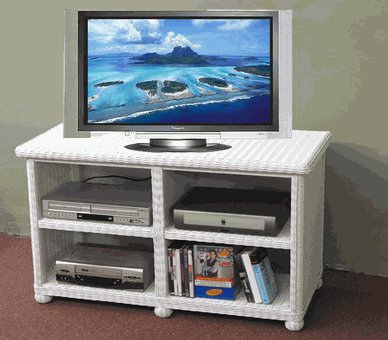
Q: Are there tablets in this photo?
A: No, there are no tablets.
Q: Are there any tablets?
A: No, there are no tablets.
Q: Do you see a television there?
A: Yes, there is a television.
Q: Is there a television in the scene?
A: Yes, there is a television.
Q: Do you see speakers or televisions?
A: Yes, there is a television.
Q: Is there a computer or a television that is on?
A: Yes, the television is on.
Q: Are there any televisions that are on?
A: Yes, there is a television that is on.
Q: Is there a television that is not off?
A: Yes, there is a television that is on.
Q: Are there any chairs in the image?
A: No, there are no chairs.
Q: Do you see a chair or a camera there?
A: No, there are no chairs or cameras.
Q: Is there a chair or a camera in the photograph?
A: No, there are no chairs or cameras.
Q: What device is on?
A: The device is a television.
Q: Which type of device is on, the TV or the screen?
A: The TV is on.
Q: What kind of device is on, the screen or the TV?
A: The TV is on.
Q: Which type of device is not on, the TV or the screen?
A: The screen is not on.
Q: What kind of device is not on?
A: The device is a screen.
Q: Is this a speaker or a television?
A: This is a television.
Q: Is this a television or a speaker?
A: This is a television.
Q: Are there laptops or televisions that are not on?
A: No, there is a television but it is on.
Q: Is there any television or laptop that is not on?
A: No, there is a television but it is on.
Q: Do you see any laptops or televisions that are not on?
A: No, there is a television but it is on.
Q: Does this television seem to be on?
A: Yes, the television is on.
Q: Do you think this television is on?
A: Yes, the television is on.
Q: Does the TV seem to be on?
A: Yes, the TV is on.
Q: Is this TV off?
A: No, the TV is on.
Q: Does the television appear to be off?
A: No, the television is on.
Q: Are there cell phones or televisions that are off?
A: No, there is a television but it is on.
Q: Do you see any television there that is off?
A: No, there is a television but it is on.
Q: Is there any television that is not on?
A: No, there is a television but it is on.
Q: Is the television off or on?
A: The television is on.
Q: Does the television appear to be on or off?
A: The television is on.